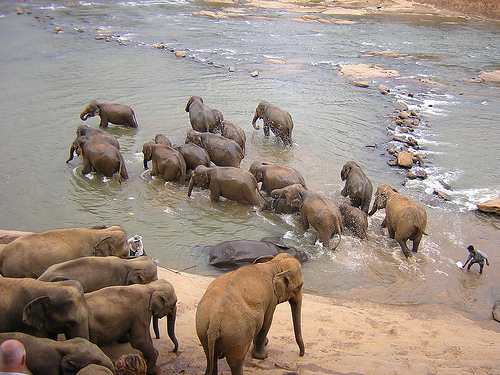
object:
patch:
[336, 62, 401, 80]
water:
[0, 0, 500, 335]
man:
[462, 245, 490, 275]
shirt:
[466, 249, 488, 262]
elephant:
[187, 164, 268, 206]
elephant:
[270, 183, 345, 252]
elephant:
[338, 202, 371, 242]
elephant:
[368, 184, 431, 264]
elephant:
[340, 160, 374, 216]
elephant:
[194, 251, 306, 375]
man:
[126, 234, 149, 257]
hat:
[132, 234, 143, 242]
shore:
[0, 229, 500, 375]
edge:
[0, 225, 499, 327]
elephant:
[80, 99, 140, 129]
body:
[99, 103, 132, 125]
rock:
[397, 151, 414, 169]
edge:
[397, 152, 401, 165]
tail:
[331, 219, 342, 251]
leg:
[250, 299, 277, 361]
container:
[456, 260, 466, 268]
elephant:
[206, 238, 310, 271]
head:
[466, 245, 474, 254]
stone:
[174, 51, 186, 58]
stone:
[16, 7, 25, 15]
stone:
[55, 26, 62, 31]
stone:
[228, 66, 235, 72]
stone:
[250, 70, 259, 77]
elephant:
[0, 223, 133, 279]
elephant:
[37, 253, 160, 294]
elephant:
[82, 278, 180, 375]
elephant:
[0, 277, 90, 342]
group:
[65, 95, 431, 271]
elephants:
[79, 98, 143, 129]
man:
[1, 338, 31, 375]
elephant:
[251, 100, 296, 149]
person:
[109, 352, 150, 375]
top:
[114, 352, 141, 363]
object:
[417, 54, 435, 59]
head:
[0, 338, 30, 374]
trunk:
[288, 286, 305, 357]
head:
[20, 280, 91, 342]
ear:
[20, 294, 53, 332]